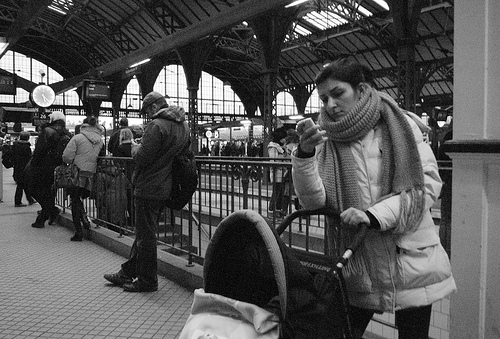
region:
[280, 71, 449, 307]
the woman has a scarf on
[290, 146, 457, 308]
the jacket is white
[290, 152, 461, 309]
the jacket is puffed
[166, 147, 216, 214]
the bag is black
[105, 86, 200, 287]
the person is on her phone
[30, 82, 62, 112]
the clock is 5.30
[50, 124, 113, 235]
the woman is leaning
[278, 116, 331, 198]
the phone is on her hand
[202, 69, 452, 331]
she is holding a baby stroller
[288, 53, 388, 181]
A WOMAN LOOKING AT HER PHONE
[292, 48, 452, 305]
WOMAN DRESSED FOR COLD WEATHER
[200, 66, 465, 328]
A WOMAN LEANING ON STROLLER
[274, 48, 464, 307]
A WOMAN WITH WINTER COAT AND SCARF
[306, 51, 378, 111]
A WOMAN WITH DARK HAIR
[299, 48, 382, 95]
DARK HAIR IN A PONY TAIL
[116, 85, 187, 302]
A MAN WITH A BACKPACK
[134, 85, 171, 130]
A MAN WITH A HAT ON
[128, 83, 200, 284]
A MAN LEANING AGAINST A RAIL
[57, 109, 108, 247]
A WOMAN IN A DRESS WITH WINTER BOOTS ON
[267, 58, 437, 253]
person looking at her phone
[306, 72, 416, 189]
person wearing a scarf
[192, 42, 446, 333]
woman holding onto a stroller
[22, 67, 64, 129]
clock hanging on the wall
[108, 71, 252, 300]
man leaning against the railing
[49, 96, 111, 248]
person holding a bag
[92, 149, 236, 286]
stairs leading down a floor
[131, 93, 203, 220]
man holding a back pack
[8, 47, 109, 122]
window on the building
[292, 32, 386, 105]
person has dark hair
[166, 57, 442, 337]
woman with a baby stroller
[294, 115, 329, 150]
woman holding a phone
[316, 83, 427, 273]
woman wearing a scarf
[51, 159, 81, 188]
woman holding a large purse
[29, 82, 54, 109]
glowing white clock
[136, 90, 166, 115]
man wearing a hat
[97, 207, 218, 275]
stairs leading underground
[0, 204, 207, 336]
tiled floor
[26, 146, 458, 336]
metal railing behind a woman with a stroller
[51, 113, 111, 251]
woman with a large purse leaning on a railing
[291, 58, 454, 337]
woman holding cell phone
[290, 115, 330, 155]
cell phone in hand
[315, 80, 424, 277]
scarf with fringed ends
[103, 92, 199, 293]
man wearing black backpack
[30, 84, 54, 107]
clock is above man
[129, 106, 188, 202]
man wearing jacket with hoodie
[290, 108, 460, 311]
woman wearing white coat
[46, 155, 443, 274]
fence with metal bars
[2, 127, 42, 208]
woman holing a backpack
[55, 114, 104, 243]
woman wearing ponytail